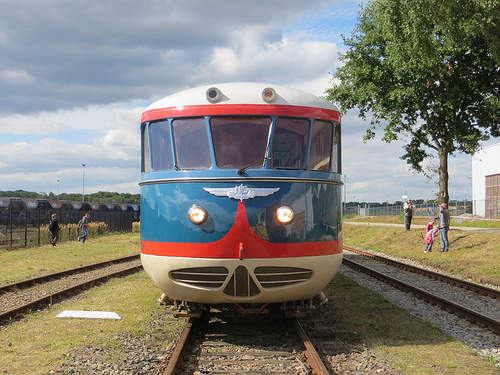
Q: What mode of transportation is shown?
A: Train.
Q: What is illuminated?
A: Lights on the train.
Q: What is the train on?
A: Tracks.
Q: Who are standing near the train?
A: The people.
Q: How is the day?
A: Overcast with clouds.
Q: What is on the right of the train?
A: Tree with lots of leaves.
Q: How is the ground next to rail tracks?
A: Rocks and grass mixed together.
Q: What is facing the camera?
A: A train.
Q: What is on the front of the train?
A: Windows.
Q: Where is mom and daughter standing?
A: Near the big tree on the side.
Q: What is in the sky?
A: Big clouds.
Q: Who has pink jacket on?
A: Little girl.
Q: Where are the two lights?
A: In front of train.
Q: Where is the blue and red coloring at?
A: Front of train.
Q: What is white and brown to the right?
A: Building.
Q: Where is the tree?
A: On right side of train.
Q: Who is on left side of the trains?
A: 2 men.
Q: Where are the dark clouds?
A: Sky.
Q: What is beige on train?
A: Fender of train.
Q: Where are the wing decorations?
A: Front of train.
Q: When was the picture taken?
A: Daytime.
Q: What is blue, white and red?
A: Train.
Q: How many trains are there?
A: One.